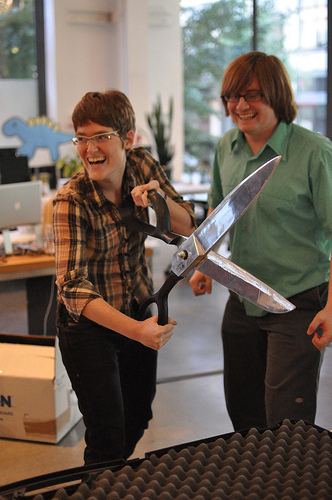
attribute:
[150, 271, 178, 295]
handle — black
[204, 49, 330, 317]
man shirt — green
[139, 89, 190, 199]
plant — green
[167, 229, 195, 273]
dinosaur — blue and yellow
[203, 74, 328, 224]
woman — wolding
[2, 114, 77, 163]
dinosaur — black, yellow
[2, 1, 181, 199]
wall — black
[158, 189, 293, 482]
scissors — grey, metal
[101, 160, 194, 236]
handle — black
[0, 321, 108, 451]
cardboard box — tan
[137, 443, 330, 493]
padding — bumpy, grey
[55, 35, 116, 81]
wall — black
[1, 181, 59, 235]
laptop — grey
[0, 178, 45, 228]
laptop — grey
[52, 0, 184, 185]
wall — white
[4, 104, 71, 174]
dinosaur — blue and yellow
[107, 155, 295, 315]
scissors — giant, pair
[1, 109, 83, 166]
dinosaur — blue and yellow